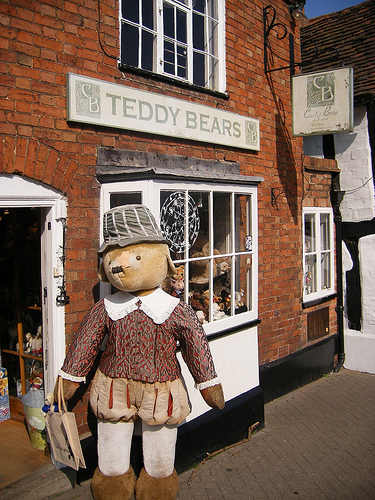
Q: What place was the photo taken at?
A: It was taken at the store.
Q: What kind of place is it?
A: It is a store.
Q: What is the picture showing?
A: It is showing a store.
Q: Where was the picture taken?
A: It was taken at the store.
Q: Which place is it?
A: It is a store.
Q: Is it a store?
A: Yes, it is a store.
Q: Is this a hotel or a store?
A: It is a store.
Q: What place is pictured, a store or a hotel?
A: It is a store.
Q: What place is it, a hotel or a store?
A: It is a store.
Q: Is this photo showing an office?
A: No, the picture is showing a store.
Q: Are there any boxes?
A: No, there are no boxes.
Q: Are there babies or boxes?
A: No, there are no boxes or babies.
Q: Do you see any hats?
A: Yes, there is a hat.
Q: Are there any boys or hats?
A: Yes, there is a hat.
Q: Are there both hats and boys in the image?
A: No, there is a hat but no boys.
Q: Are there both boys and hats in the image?
A: No, there is a hat but no boys.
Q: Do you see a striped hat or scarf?
A: Yes, there is a striped hat.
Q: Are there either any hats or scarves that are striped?
A: Yes, the hat is striped.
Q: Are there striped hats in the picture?
A: Yes, there is a striped hat.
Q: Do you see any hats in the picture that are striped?
A: Yes, there is a hat that is striped.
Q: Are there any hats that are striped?
A: Yes, there is a hat that is striped.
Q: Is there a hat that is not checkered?
A: Yes, there is a striped hat.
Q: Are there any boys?
A: No, there are no boys.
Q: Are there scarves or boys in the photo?
A: No, there are no boys or scarves.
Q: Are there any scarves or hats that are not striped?
A: No, there is a hat but it is striped.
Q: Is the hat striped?
A: Yes, the hat is striped.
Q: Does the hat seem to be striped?
A: Yes, the hat is striped.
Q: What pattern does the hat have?
A: The hat has striped pattern.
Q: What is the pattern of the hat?
A: The hat is striped.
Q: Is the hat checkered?
A: No, the hat is striped.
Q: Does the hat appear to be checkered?
A: No, the hat is striped.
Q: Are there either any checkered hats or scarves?
A: No, there is a hat but it is striped.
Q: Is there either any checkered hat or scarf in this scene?
A: No, there is a hat but it is striped.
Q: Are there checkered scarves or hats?
A: No, there is a hat but it is striped.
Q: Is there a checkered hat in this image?
A: No, there is a hat but it is striped.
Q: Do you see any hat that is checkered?
A: No, there is a hat but it is striped.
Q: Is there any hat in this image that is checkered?
A: No, there is a hat but it is striped.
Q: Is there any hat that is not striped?
A: No, there is a hat but it is striped.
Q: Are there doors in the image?
A: Yes, there is a door.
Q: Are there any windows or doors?
A: Yes, there is a door.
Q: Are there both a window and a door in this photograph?
A: Yes, there are both a door and a window.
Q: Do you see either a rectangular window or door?
A: Yes, there is a rectangular door.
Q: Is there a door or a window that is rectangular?
A: Yes, the door is rectangular.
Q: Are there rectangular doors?
A: Yes, there is a rectangular door.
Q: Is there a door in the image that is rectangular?
A: Yes, there is a door that is rectangular.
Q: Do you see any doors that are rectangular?
A: Yes, there is a door that is rectangular.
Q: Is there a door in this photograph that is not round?
A: Yes, there is a rectangular door.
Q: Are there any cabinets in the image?
A: No, there are no cabinets.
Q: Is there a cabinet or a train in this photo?
A: No, there are no cabinets or trains.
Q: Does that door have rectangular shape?
A: Yes, the door is rectangular.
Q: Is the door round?
A: No, the door is rectangular.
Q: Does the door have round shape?
A: No, the door is rectangular.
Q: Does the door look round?
A: No, the door is rectangular.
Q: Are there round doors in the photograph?
A: No, there is a door but it is rectangular.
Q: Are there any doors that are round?
A: No, there is a door but it is rectangular.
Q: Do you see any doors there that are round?
A: No, there is a door but it is rectangular.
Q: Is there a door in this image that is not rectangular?
A: No, there is a door but it is rectangular.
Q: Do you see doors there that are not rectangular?
A: No, there is a door but it is rectangular.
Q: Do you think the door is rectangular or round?
A: The door is rectangular.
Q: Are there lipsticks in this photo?
A: No, there are no lipsticks.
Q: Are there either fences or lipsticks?
A: No, there are no lipsticks or fences.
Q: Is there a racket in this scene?
A: No, there are no rackets.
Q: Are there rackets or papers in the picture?
A: No, there are no rackets or papers.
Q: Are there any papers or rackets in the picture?
A: No, there are no rackets or papers.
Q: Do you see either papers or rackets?
A: No, there are no rackets or papers.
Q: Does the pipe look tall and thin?
A: Yes, the pipe is tall and thin.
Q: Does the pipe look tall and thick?
A: No, the pipe is tall but thin.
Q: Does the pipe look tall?
A: Yes, the pipe is tall.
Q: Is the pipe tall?
A: Yes, the pipe is tall.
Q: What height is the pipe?
A: The pipe is tall.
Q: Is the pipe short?
A: No, the pipe is tall.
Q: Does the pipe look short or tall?
A: The pipe is tall.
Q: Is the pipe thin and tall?
A: Yes, the pipe is thin and tall.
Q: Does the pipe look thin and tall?
A: Yes, the pipe is thin and tall.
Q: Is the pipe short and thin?
A: No, the pipe is thin but tall.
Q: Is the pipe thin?
A: Yes, the pipe is thin.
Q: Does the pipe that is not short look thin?
A: Yes, the pipe is thin.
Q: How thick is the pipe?
A: The pipe is thin.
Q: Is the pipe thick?
A: No, the pipe is thin.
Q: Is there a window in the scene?
A: Yes, there is a window.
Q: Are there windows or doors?
A: Yes, there is a window.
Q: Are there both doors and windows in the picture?
A: Yes, there are both a window and a door.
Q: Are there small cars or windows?
A: Yes, there is a small window.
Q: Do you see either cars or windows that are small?
A: Yes, the window is small.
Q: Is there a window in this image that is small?
A: Yes, there is a small window.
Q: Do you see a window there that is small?
A: Yes, there is a window that is small.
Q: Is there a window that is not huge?
A: Yes, there is a small window.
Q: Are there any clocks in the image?
A: No, there are no clocks.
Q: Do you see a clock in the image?
A: No, there are no clocks.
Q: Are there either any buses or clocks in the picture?
A: No, there are no clocks or buses.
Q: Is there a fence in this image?
A: No, there are no fences.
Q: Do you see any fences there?
A: No, there are no fences.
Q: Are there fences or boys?
A: No, there are no fences or boys.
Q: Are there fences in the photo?
A: No, there are no fences.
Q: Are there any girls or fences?
A: No, there are no fences or girls.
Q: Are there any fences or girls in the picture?
A: No, there are no fences or girls.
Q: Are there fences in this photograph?
A: No, there are no fences.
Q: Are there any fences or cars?
A: No, there are no fences or cars.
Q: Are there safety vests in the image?
A: No, there are no safety vests.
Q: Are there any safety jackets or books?
A: No, there are no safety jackets or books.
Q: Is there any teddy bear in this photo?
A: Yes, there is a teddy bear.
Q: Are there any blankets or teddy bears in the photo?
A: Yes, there is a teddy bear.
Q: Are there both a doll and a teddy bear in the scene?
A: No, there is a teddy bear but no dolls.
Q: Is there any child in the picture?
A: No, there are no children.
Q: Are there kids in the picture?
A: No, there are no kids.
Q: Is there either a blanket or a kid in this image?
A: No, there are no children or blankets.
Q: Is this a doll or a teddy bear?
A: This is a teddy bear.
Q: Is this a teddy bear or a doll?
A: This is a teddy bear.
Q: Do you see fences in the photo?
A: No, there are no fences.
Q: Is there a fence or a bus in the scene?
A: No, there are no fences or buses.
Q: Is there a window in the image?
A: Yes, there is a window.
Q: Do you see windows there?
A: Yes, there is a window.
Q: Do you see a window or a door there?
A: Yes, there is a window.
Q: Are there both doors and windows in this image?
A: Yes, there are both a window and a door.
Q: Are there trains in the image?
A: No, there are no trains.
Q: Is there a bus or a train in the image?
A: No, there are no trains or buses.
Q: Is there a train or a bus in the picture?
A: No, there are no trains or buses.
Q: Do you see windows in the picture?
A: Yes, there is a window.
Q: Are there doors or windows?
A: Yes, there is a window.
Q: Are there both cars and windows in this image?
A: No, there is a window but no cars.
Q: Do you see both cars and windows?
A: No, there is a window but no cars.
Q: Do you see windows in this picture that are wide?
A: Yes, there is a wide window.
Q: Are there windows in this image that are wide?
A: Yes, there is a window that is wide.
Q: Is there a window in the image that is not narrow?
A: Yes, there is a wide window.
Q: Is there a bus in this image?
A: No, there are no buses.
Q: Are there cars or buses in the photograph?
A: No, there are no buses or cars.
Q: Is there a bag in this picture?
A: Yes, there is a bag.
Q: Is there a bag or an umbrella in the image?
A: Yes, there is a bag.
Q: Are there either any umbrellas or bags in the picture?
A: Yes, there is a bag.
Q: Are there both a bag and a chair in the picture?
A: No, there is a bag but no chairs.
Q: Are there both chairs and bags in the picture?
A: No, there is a bag but no chairs.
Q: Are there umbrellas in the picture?
A: No, there are no umbrellas.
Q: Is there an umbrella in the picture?
A: No, there are no umbrellas.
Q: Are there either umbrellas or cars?
A: No, there are no umbrellas or cars.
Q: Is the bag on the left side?
A: Yes, the bag is on the left of the image.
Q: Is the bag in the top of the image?
A: No, the bag is in the bottom of the image.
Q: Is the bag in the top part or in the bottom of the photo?
A: The bag is in the bottom of the image.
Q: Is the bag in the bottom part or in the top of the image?
A: The bag is in the bottom of the image.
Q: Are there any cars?
A: No, there are no cars.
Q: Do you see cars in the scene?
A: No, there are no cars.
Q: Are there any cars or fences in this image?
A: No, there are no cars or fences.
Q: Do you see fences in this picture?
A: No, there are no fences.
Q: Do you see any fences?
A: No, there are no fences.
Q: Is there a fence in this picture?
A: No, there are no fences.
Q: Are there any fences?
A: No, there are no fences.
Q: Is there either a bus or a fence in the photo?
A: No, there are no fences or buses.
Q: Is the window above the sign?
A: No, the sign is above the window.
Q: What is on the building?
A: The sign is on the building.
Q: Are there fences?
A: No, there are no fences.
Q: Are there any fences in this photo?
A: No, there are no fences.